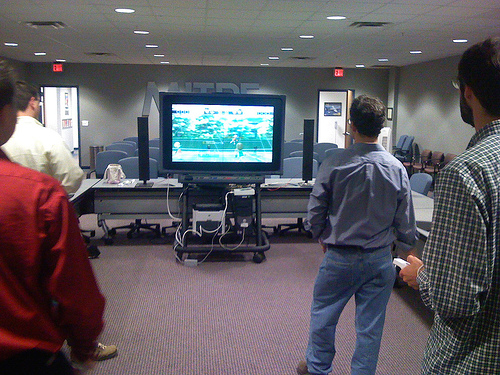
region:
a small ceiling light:
[301, 34, 316, 39]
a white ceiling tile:
[205, 5, 258, 22]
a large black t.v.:
[157, 87, 289, 167]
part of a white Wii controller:
[388, 255, 409, 269]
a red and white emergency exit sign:
[52, 60, 63, 72]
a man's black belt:
[332, 240, 365, 253]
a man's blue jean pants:
[308, 240, 395, 373]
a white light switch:
[79, 118, 90, 128]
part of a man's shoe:
[94, 335, 120, 357]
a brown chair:
[420, 148, 444, 175]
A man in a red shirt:
[1, 58, 108, 373]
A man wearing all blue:
[296, 94, 419, 374]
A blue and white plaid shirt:
[419, 118, 499, 374]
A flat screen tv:
[157, 89, 286, 179]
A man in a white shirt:
[1, 79, 85, 199]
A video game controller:
[393, 257, 408, 268]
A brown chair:
[423, 150, 443, 180]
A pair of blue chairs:
[392, 133, 414, 161]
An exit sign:
[50, 61, 64, 72]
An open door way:
[316, 89, 354, 151]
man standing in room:
[3, 78, 88, 373]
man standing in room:
[298, 94, 417, 374]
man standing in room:
[392, 48, 497, 368]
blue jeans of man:
[303, 240, 388, 370]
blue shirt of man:
[307, 140, 420, 251]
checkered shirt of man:
[418, 124, 498, 374]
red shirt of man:
[3, 153, 100, 361]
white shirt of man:
[4, 117, 80, 188]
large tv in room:
[157, 93, 288, 173]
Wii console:
[232, 186, 256, 196]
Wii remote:
[393, 253, 413, 274]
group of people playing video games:
[0, 40, 499, 372]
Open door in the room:
[39, 84, 81, 171]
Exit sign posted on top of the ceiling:
[49, 62, 64, 73]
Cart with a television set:
[156, 88, 286, 264]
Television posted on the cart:
[159, 88, 284, 173]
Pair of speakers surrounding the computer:
[134, 112, 318, 187]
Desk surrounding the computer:
[59, 163, 439, 270]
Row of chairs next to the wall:
[389, 133, 451, 186]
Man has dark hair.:
[355, 105, 394, 132]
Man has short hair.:
[354, 95, 378, 132]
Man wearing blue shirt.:
[336, 169, 398, 219]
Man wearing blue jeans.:
[309, 264, 373, 314]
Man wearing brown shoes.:
[293, 358, 313, 373]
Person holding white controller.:
[388, 250, 420, 280]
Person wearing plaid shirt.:
[434, 243, 463, 300]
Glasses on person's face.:
[447, 77, 472, 91]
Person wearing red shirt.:
[8, 213, 76, 280]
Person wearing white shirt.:
[26, 130, 63, 164]